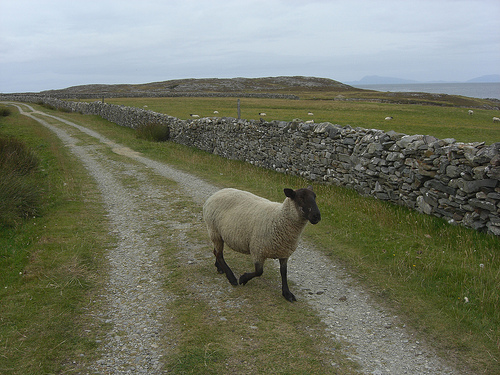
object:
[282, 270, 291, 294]
black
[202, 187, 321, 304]
sheep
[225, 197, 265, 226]
fur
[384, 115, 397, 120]
sheep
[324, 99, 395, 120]
field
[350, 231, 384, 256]
green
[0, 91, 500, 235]
wall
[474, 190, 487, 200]
rocks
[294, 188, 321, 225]
face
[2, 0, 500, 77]
skies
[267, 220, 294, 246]
white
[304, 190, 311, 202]
brown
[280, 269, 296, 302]
leg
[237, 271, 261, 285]
leg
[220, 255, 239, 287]
leg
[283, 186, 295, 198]
ear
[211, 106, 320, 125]
flock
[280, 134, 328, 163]
stone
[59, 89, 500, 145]
pasture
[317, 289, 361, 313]
dirt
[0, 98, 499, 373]
road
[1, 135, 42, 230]
bushes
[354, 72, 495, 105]
mountains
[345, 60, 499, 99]
distance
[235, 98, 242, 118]
post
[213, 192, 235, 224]
wool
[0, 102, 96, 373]
grass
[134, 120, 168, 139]
bush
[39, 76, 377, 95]
hills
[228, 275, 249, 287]
feet